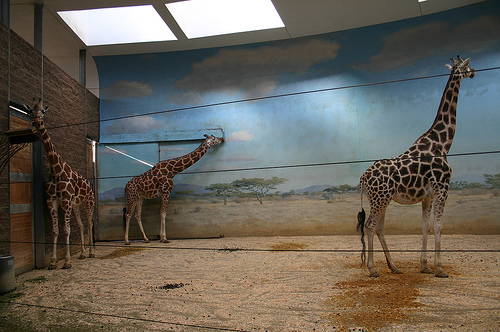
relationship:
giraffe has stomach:
[346, 46, 482, 287] [386, 180, 422, 209]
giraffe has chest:
[22, 90, 96, 271] [37, 149, 69, 210]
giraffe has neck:
[113, 125, 227, 246] [166, 144, 209, 178]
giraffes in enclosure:
[17, 53, 478, 283] [0, 0, 500, 174]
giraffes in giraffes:
[17, 53, 478, 283] [20, 55, 478, 278]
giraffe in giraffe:
[113, 125, 227, 246] [121, 127, 226, 246]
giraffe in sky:
[113, 125, 227, 246] [101, 67, 359, 174]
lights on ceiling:
[50, 1, 291, 51] [17, 3, 382, 53]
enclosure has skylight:
[4, 4, 498, 329] [48, 3, 298, 55]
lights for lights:
[54, 0, 290, 49] [54, 0, 290, 49]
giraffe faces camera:
[22, 90, 107, 279] [1, 1, 497, 326]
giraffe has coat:
[113, 125, 227, 246] [130, 174, 170, 203]